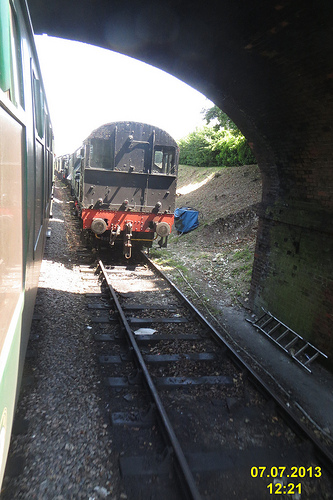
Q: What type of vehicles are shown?
A: Trains.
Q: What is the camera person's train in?
A: Tunnel.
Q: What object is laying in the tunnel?
A: Ladder.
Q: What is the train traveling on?
A: The metal rails.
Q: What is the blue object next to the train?
A: A bag.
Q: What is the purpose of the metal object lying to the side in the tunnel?
A: Letting people climb to high places.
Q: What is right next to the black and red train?
A: Another train.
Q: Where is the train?
A: On the tracks.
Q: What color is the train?
A: Black and red.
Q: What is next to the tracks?
A: Gravel.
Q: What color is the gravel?
A: Gray.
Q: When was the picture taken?
A: Daytime.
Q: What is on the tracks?
A: The train.